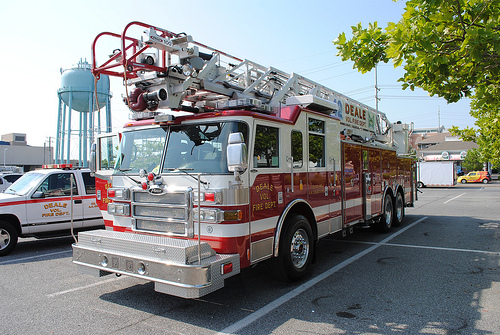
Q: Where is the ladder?
A: On top of the fire truck.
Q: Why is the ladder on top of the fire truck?
A: It is not in use.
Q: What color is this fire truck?
A: Red.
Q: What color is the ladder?
A: White.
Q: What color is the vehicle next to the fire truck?
A: White.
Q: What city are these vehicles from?
A: Deale.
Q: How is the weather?
A: Sunny.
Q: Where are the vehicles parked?
A: In a parking lot.